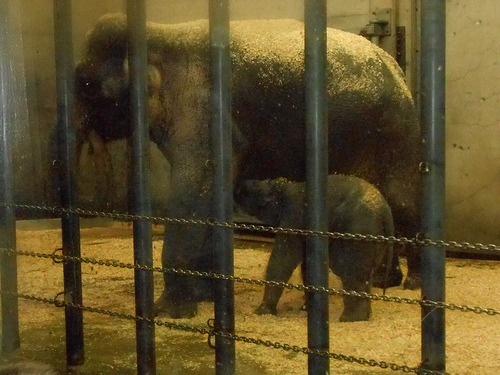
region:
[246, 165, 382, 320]
baby elephant under its mom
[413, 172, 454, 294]
big bars on elephant pen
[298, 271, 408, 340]
chain in front of elephant pen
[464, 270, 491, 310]
straw on floor of pen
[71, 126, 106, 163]
elephant with broken tusk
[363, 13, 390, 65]
lock on pen door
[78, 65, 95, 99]
eye of gray elephant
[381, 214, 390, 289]
long tail of baby elephant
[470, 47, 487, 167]
cracked gray wall of pen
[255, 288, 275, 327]
flat foot of baby elephant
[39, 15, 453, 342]
two elephants standing up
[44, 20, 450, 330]
elephants behind bars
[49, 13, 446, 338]
a baby elephant with an adult elephant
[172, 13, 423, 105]
dirt on the elephant's back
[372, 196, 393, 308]
skinny gray tail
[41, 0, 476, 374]
five black bars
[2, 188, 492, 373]
row of three chains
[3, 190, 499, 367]
chains running along the bars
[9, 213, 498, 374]
dirt on the ground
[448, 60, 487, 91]
crack in the wall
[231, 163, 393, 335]
This is an elephant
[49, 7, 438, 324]
This is an elephant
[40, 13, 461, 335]
These are two elephants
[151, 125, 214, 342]
Leg of an elephant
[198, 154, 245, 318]
Leg of an elephant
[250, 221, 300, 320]
Leg of an elephant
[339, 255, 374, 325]
Leg of an elephant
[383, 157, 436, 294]
Leg of an elephant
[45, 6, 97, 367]
This is a metal bar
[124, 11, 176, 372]
This is a metal bar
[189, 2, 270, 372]
Large grey metal post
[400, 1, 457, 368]
Large grey metal post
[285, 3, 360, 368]
Large grey metal post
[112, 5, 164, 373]
Large grey metal post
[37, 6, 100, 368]
Large grey metal post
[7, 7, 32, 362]
Large grey metal post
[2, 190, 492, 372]
Dark chain wired fencing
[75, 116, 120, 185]
Large tusk of an elephant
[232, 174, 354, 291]
Small baby elephant feeding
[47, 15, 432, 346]
Large elephant feeding small elephant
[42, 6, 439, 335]
Adult and baby elephant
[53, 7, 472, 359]
Bars in the foreground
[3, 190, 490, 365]
Chains on the bars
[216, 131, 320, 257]
Baby elephant is nursing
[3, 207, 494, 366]
Hay and dust on the floor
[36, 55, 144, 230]
Adult elephant is eating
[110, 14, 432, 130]
Adult has hay on its back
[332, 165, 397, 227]
Baby has some hay on its back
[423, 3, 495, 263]
Back wall is concrete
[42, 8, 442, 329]
Adult elephant is bigger than the baby